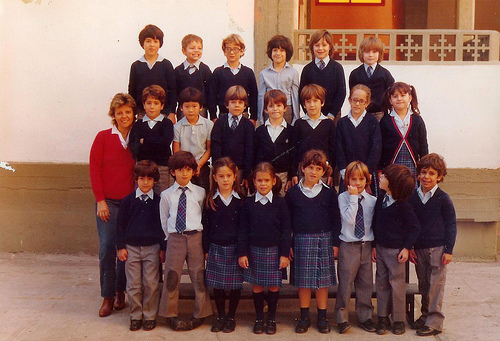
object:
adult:
[88, 90, 137, 317]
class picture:
[11, 9, 496, 341]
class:
[142, 27, 442, 211]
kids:
[253, 87, 302, 197]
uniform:
[127, 56, 177, 118]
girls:
[200, 156, 246, 333]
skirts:
[203, 241, 245, 290]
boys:
[159, 150, 214, 332]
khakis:
[125, 239, 163, 321]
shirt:
[88, 124, 137, 202]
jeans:
[93, 195, 133, 299]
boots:
[98, 296, 115, 318]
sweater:
[113, 188, 169, 252]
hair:
[107, 92, 140, 129]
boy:
[333, 160, 379, 334]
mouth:
[259, 187, 269, 191]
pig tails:
[409, 83, 421, 114]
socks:
[298, 306, 311, 319]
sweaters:
[348, 62, 397, 113]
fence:
[296, 28, 496, 61]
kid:
[256, 34, 301, 128]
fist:
[345, 184, 358, 197]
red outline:
[398, 126, 410, 153]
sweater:
[377, 105, 431, 174]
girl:
[376, 80, 430, 188]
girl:
[331, 82, 383, 193]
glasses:
[348, 97, 368, 106]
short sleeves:
[170, 113, 215, 164]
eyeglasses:
[225, 47, 241, 52]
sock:
[250, 288, 266, 319]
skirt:
[290, 232, 338, 290]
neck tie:
[183, 63, 194, 77]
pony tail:
[325, 161, 333, 176]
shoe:
[263, 317, 278, 335]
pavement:
[461, 283, 488, 326]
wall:
[0, 2, 498, 260]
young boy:
[355, 35, 394, 87]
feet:
[415, 319, 442, 336]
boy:
[170, 34, 215, 124]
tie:
[365, 62, 375, 76]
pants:
[333, 239, 375, 323]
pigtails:
[275, 174, 283, 194]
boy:
[172, 85, 216, 195]